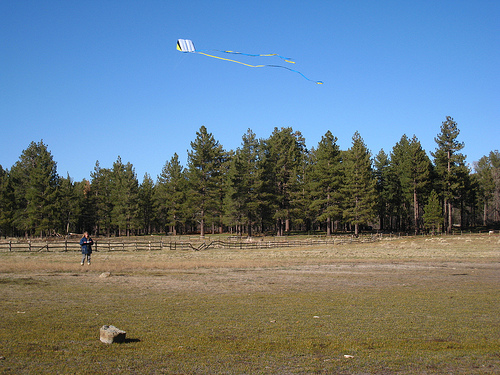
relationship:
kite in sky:
[175, 38, 321, 85] [1, 1, 496, 184]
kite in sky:
[175, 38, 321, 85] [3, 2, 496, 154]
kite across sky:
[175, 38, 321, 85] [1, 1, 496, 184]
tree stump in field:
[99, 324, 125, 344] [135, 285, 359, 344]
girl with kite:
[80, 231, 94, 266] [159, 14, 334, 121]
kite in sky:
[173, 36, 202, 54] [301, 0, 498, 136]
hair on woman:
[79, 229, 89, 239] [77, 227, 97, 267]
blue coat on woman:
[79, 236, 93, 256] [76, 229, 103, 276]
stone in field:
[96, 322, 128, 345] [0, 232, 499, 373]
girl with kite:
[80, 231, 94, 266] [168, 33, 308, 81]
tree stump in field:
[93, 316, 130, 351] [0, 232, 499, 373]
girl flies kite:
[78, 230, 93, 264] [175, 38, 321, 85]